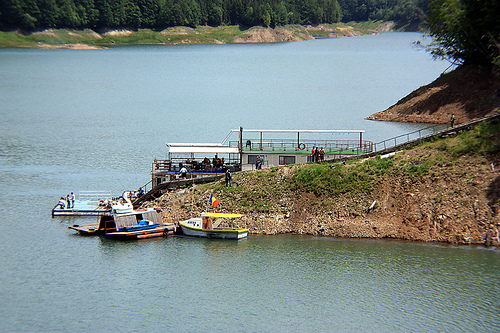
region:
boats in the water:
[99, 210, 257, 248]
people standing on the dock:
[58, 192, 78, 208]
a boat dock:
[51, 194, 115, 216]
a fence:
[327, 120, 478, 140]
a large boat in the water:
[157, 134, 355, 172]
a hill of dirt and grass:
[166, 157, 496, 259]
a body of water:
[6, 47, 493, 331]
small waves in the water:
[320, 241, 498, 313]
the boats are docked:
[10, 205, 254, 237]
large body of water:
[140, 64, 247, 104]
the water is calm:
[285, 281, 376, 317]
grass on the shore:
[280, 161, 357, 198]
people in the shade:
[171, 159, 236, 175]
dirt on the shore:
[375, 213, 408, 233]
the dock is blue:
[77, 201, 85, 207]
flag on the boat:
[187, 188, 219, 210]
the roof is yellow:
[217, 213, 234, 220]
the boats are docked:
[53, 195, 245, 246]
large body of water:
[105, 260, 272, 303]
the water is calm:
[290, 282, 376, 314]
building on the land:
[225, 125, 359, 167]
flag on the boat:
[196, 195, 225, 210]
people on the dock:
[46, 188, 103, 215]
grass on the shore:
[88, 26, 240, 55]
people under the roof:
[167, 148, 235, 173]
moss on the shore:
[294, 167, 375, 203]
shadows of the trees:
[411, 78, 463, 107]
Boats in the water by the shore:
[70, 197, 252, 245]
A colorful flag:
[205, 193, 217, 209]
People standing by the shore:
[311, 143, 330, 165]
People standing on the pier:
[172, 148, 232, 178]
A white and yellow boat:
[177, 208, 245, 238]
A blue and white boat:
[109, 217, 164, 238]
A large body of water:
[2, 31, 476, 331]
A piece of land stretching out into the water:
[140, 127, 499, 242]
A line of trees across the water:
[5, 1, 355, 28]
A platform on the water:
[53, 192, 117, 215]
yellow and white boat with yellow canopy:
[179, 208, 247, 239]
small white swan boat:
[111, 191, 134, 213]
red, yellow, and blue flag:
[208, 195, 219, 210]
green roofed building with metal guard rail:
[225, 128, 371, 170]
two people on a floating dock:
[66, 191, 76, 209]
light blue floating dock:
[54, 190, 108, 213]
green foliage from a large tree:
[414, 3, 497, 69]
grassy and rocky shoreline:
[140, 113, 498, 248]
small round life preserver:
[296, 141, 306, 151]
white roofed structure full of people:
[151, 140, 242, 177]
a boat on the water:
[179, 204, 250, 241]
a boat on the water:
[98, 203, 173, 245]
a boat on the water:
[164, 131, 361, 163]